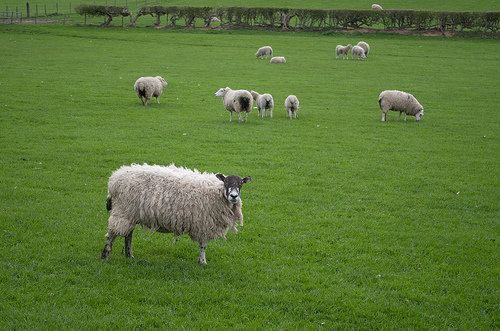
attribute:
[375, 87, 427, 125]
sheep — staring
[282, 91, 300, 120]
sheep — staring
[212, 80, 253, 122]
sheep — staring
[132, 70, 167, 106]
sheep — staring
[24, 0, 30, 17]
pole — black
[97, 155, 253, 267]
sheep — staring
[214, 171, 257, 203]
head — black, white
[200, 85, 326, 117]
sheep — gray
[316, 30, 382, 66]
sheep — grazing, white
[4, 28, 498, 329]
lawn — large, grass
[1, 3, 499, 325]
grass — short, green, Brown, green-and-brown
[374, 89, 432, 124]
sheep — grazing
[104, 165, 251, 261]
sheep — white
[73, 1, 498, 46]
trees — short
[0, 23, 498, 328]
green grass — short, brown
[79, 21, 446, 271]
herd — small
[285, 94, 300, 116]
sheep — gray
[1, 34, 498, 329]
field — green